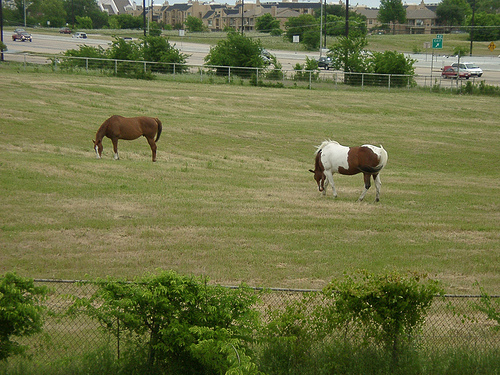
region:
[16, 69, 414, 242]
two horses in a pasture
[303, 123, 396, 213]
a horse in a pasture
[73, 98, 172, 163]
a horse in a pasture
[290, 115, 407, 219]
a horse eating grass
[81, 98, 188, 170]
a horse eating grass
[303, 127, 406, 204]
a white and brown horse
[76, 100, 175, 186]
a white and brown horse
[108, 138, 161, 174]
the four legs of a horse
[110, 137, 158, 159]
the legs of a horse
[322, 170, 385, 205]
the legs of a horse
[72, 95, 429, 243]
Two horses grazing in a field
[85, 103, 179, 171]
A brown horse eating some grass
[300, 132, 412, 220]
A white and brown horse eating the grass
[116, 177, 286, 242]
Short green grass grows in the field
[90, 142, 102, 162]
A small white stripe on the horse's head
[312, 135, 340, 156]
A short white mane on the horse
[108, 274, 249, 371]
Small green bushes by the fence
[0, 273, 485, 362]
A short chain link fence by the field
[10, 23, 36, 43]
A red car driving along the road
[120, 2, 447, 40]
A row of buildings in the distance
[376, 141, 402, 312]
part of a fence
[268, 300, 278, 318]
edge of a fence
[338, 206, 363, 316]
part of a twig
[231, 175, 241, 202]
part of a garden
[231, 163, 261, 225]
part of a field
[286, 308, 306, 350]
edge of a fence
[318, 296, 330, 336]
part of a garden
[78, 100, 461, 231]
Two horses are here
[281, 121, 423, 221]
This is a brown and white horse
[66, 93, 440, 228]
Horses are standing on the ground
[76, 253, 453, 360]
These are green leaves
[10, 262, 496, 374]
Gates grey here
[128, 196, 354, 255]
The grass is short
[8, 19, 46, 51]
Truck is in motion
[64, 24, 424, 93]
These are tall trees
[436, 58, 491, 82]
red and white vehicle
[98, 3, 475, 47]
Buildings in the background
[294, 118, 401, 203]
This is a horse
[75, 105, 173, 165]
This is a horse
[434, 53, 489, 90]
This is a car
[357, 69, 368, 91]
This is a pole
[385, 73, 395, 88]
This is a pole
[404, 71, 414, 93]
This is a pole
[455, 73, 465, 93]
This is a pole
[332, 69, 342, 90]
This is a pole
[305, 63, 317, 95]
This is a pole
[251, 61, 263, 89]
This is a pole